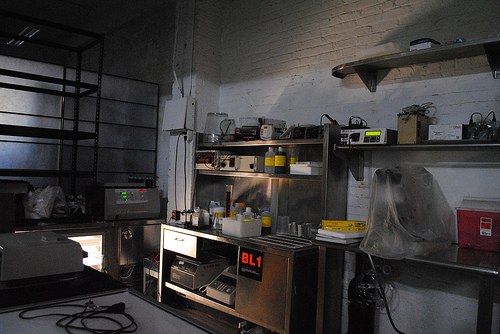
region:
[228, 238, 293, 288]
red and black "BL1" sign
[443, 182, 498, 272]
medical waste disposal bin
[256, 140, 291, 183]
bottles with yellow labels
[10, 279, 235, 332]
loose black cord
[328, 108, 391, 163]
device with a green LED display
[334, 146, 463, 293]
translucent plastic cover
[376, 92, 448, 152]
tan cardboard box on a shelf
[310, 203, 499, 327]
stainless steel metal table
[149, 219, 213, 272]
closed stainless steel drawer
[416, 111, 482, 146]
white box on a shelf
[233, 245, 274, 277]
orange letters in the photo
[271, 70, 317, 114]
wall in the background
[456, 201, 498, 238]
red and white object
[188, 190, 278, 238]
many items on top of something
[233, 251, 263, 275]
The letters B and L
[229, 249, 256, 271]
Two capital letters in orange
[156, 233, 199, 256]
handle to a drawer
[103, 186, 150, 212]
red and green lights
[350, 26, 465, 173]
two different shelves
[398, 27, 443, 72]
item on a high shelf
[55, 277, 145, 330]
a very long cable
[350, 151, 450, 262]
a machine cover in plastic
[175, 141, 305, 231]
lots of labled bottles with liquids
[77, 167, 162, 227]
a very strange looking machine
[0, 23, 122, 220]
a tall tool rack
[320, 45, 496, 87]
self with some items on top of it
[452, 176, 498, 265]
a mysterious red box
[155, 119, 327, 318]
a workstation with lots of items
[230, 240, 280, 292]
a strange sign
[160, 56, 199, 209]
power and 2 chords that are pluged in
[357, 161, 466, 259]
a item covered with a tarp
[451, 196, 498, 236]
red cautions and safety cooler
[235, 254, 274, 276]
BL1 in red bold text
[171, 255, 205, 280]
a scale underneath a station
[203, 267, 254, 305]
a tan cash register under station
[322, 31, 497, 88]
a silver shelf on the wall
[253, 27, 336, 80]
white brick dingy wall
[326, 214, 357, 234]
a yellow box of aluminmum paper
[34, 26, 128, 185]
a black metal tier shelf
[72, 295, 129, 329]
a black cord with no connection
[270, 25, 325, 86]
white paint on brick wall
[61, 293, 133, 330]
black cable on floor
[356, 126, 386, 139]
yellow screen of digital display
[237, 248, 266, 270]
red letters and number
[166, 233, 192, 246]
handle on metal draw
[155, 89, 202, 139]
white box on wall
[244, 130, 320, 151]
edge of metal shelf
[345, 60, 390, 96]
brace under metal shelf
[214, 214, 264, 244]
white square container on metal